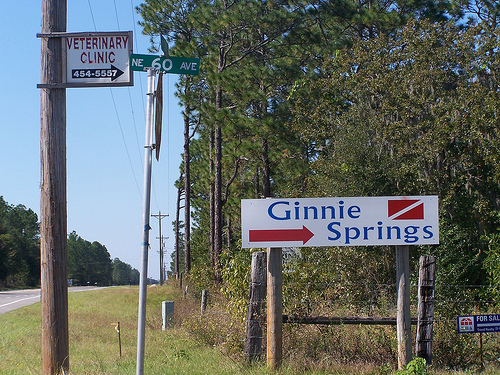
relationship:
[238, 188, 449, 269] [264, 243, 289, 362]
sign on wood post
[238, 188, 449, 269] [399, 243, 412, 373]
sign on wood post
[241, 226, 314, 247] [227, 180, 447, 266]
arrow on white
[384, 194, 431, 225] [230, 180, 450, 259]
block on sign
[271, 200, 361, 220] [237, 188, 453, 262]
writing on sign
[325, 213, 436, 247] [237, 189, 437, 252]
writing on sign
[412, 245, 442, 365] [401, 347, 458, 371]
post in ground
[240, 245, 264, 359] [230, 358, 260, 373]
wood post in ground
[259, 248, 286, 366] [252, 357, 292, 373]
wood post in ground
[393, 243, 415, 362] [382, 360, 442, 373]
wood post in ground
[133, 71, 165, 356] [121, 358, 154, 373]
post on ground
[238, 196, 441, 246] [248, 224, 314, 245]
sign has a arrow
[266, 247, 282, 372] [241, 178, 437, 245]
pole holding sign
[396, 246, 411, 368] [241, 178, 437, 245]
pole holding sign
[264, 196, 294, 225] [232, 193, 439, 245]
g on sign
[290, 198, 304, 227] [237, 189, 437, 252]
i on sign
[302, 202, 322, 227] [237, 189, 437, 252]
n on sign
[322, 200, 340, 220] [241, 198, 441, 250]
n on sign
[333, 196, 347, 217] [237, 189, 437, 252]
i on sign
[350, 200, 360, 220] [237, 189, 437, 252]
e on sign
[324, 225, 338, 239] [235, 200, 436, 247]
s on sign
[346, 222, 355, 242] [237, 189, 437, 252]
p on sign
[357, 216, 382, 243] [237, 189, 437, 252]
r on sign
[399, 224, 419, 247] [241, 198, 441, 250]
g on sign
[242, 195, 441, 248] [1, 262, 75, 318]
post on side of road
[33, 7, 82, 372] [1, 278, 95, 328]
pole on side of road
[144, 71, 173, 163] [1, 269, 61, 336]
stop sign on side of road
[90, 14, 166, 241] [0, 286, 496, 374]
wire on side of ground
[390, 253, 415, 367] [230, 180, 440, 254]
pole beneath sign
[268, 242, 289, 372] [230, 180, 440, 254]
pole beneath sign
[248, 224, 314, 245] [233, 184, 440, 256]
arrow on post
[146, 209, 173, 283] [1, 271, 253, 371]
pole in grass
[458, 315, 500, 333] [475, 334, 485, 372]
sale sign on pole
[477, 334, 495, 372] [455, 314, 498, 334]
pole attached to sign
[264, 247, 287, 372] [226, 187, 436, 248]
pole attached to sign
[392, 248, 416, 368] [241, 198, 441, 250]
pole attached to sign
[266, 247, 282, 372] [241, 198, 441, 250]
pole attached to sign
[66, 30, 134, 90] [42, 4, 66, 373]
sign on pole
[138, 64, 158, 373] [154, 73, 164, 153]
pole attached to sign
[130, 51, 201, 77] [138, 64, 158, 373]
sign attached to pole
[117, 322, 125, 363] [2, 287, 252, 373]
stick in grass